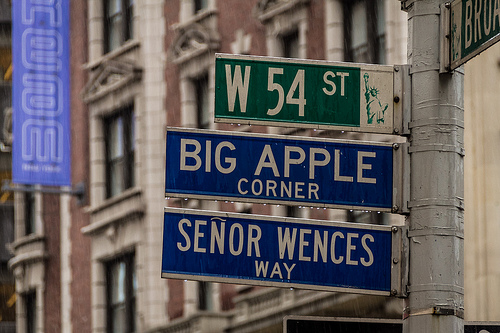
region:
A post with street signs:
[156, 2, 498, 324]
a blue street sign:
[163, 205, 404, 296]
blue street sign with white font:
[158, 213, 414, 295]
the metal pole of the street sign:
[403, 2, 480, 330]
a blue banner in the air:
[10, 0, 86, 197]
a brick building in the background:
[1, 0, 405, 332]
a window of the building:
[78, 59, 155, 208]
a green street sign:
[211, 47, 410, 132]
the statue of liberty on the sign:
[363, 62, 396, 132]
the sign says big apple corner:
[165, 125, 420, 210]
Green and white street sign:
[212, 52, 399, 129]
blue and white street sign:
[168, 131, 408, 215]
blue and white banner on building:
[14, 7, 71, 198]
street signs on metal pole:
[158, 0, 494, 318]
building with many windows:
[12, 3, 394, 323]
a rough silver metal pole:
[405, 4, 467, 329]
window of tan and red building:
[90, 109, 139, 196]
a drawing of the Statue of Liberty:
[362, 70, 393, 126]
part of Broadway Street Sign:
[454, 4, 496, 51]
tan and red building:
[0, 6, 409, 328]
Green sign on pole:
[215, 51, 407, 128]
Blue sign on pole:
[170, 123, 413, 204]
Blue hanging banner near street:
[12, 0, 74, 186]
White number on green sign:
[268, 66, 307, 118]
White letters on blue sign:
[177, 135, 383, 197]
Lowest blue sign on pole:
[162, 208, 399, 298]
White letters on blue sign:
[173, 217, 378, 277]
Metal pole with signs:
[408, 2, 460, 331]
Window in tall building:
[100, 100, 146, 189]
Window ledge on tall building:
[78, 184, 141, 231]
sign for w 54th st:
[215, 64, 368, 132]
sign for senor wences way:
[175, 213, 384, 285]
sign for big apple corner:
[157, 123, 395, 209]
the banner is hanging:
[5, 10, 83, 202]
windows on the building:
[90, 248, 145, 326]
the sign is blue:
[339, 192, 379, 200]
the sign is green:
[324, 110, 347, 119]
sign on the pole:
[427, 0, 477, 84]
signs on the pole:
[182, 60, 415, 310]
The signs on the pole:
[147, 36, 416, 304]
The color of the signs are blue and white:
[158, 124, 399, 298]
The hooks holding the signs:
[379, 60, 437, 312]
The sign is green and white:
[196, 35, 363, 127]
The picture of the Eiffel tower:
[354, 62, 390, 124]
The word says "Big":
[172, 131, 239, 177]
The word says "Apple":
[248, 140, 380, 185]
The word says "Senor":
[171, 211, 262, 264]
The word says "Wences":
[276, 223, 378, 268]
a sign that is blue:
[155, 129, 435, 218]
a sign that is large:
[127, 200, 415, 305]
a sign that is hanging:
[4, 1, 90, 202]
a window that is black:
[73, 241, 154, 332]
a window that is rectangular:
[97, 97, 154, 209]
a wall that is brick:
[47, 202, 105, 319]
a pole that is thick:
[409, 21, 473, 332]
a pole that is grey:
[391, 25, 466, 325]